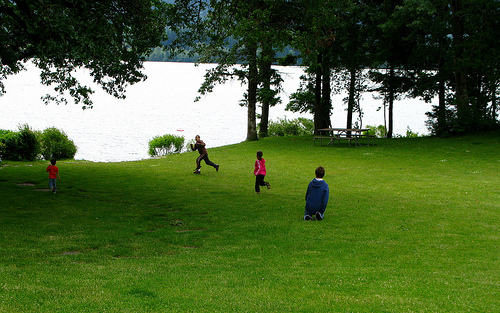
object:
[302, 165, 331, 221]
boy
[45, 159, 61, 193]
boy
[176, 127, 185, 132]
frisbee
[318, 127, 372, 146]
table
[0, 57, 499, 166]
water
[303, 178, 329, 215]
sweater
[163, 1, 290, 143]
tree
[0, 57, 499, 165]
lake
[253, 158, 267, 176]
jacket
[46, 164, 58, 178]
shirt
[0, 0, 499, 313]
park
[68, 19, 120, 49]
leaves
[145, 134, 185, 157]
plants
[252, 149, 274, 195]
child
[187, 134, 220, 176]
children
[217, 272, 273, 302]
grass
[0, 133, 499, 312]
field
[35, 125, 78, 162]
bushes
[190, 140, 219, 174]
outfit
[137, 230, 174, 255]
grass